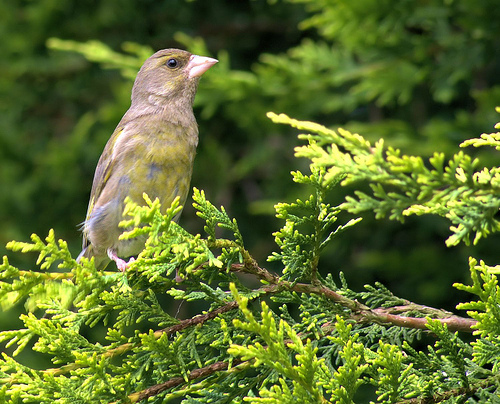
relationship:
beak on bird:
[189, 51, 219, 78] [72, 46, 222, 267]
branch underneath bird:
[170, 258, 286, 282] [72, 46, 222, 267]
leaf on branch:
[226, 281, 331, 403] [122, 316, 358, 402]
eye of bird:
[164, 56, 177, 68] [72, 46, 222, 267]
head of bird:
[130, 46, 219, 106] [72, 46, 222, 267]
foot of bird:
[106, 247, 134, 271] [72, 46, 222, 267]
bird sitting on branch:
[72, 46, 222, 267] [170, 258, 286, 282]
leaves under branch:
[2, 110, 499, 403] [170, 258, 286, 282]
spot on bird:
[146, 161, 159, 180] [72, 46, 222, 267]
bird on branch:
[72, 46, 222, 267] [159, 286, 275, 337]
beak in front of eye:
[189, 51, 219, 78] [164, 56, 177, 68]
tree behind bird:
[1, 1, 235, 266] [72, 46, 222, 267]